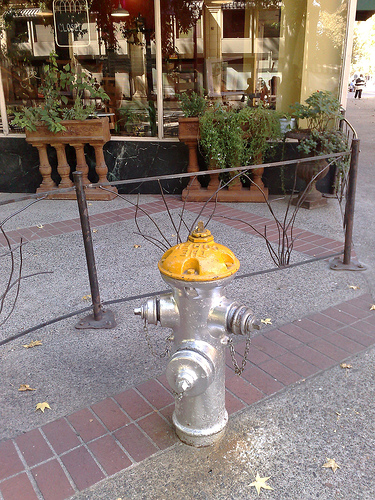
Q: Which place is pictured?
A: It is a street.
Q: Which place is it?
A: It is a street.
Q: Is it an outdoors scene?
A: Yes, it is outdoors.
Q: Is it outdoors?
A: Yes, it is outdoors.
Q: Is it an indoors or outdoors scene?
A: It is outdoors.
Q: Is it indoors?
A: No, it is outdoors.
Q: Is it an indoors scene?
A: No, it is outdoors.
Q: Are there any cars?
A: No, there are no cars.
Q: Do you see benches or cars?
A: No, there are no cars or benches.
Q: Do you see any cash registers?
A: No, there are no cash registers.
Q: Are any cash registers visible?
A: No, there are no cash registers.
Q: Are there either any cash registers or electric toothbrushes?
A: No, there are no cash registers or electric toothbrushes.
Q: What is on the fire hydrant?
A: The chain is on the fire hydrant.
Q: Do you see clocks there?
A: No, there are no clocks.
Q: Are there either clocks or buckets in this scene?
A: No, there are no clocks or buckets.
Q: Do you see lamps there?
A: No, there are no lamps.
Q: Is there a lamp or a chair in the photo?
A: No, there are no lamps or chairs.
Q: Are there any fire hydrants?
A: Yes, there is a fire hydrant.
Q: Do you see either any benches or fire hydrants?
A: Yes, there is a fire hydrant.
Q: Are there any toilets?
A: No, there are no toilets.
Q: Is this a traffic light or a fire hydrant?
A: This is a fire hydrant.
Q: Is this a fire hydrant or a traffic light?
A: This is a fire hydrant.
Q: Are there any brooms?
A: No, there are no brooms.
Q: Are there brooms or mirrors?
A: No, there are no brooms or mirrors.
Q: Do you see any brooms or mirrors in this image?
A: No, there are no brooms or mirrors.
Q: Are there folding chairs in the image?
A: No, there are no folding chairs.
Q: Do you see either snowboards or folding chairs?
A: No, there are no folding chairs or snowboards.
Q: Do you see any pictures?
A: No, there are no pictures.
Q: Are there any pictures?
A: No, there are no pictures.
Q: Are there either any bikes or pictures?
A: No, there are no pictures or bikes.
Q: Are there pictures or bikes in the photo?
A: No, there are no pictures or bikes.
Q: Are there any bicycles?
A: No, there are no bicycles.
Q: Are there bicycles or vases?
A: No, there are no bicycles or vases.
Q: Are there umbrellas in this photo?
A: No, there are no umbrellas.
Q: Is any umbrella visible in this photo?
A: No, there are no umbrellas.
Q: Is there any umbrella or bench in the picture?
A: No, there are no umbrellas or benches.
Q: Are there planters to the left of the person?
A: Yes, there is a planter to the left of the person.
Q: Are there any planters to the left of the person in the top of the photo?
A: Yes, there is a planter to the left of the person.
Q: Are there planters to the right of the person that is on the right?
A: No, the planter is to the left of the person.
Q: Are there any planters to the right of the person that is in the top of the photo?
A: No, the planter is to the left of the person.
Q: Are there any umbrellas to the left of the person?
A: No, there is a planter to the left of the person.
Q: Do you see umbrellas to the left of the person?
A: No, there is a planter to the left of the person.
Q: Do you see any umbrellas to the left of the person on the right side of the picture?
A: No, there is a planter to the left of the person.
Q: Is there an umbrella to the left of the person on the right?
A: No, there is a planter to the left of the person.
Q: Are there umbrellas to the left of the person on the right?
A: No, there is a planter to the left of the person.